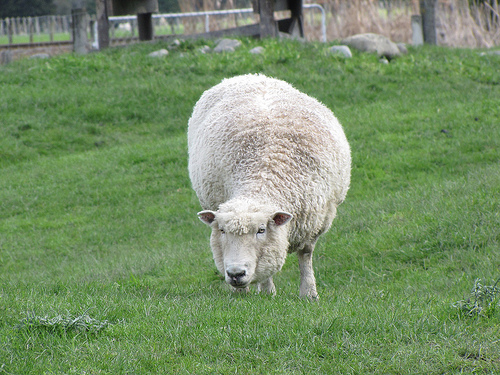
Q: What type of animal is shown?
A: Sheep.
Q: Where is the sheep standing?
A: Field.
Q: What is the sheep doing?
A: Grazing.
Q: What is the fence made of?
A: Wood.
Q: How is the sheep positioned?
A: Standing.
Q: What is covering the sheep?
A: Wool.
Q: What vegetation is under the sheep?
A: Grass.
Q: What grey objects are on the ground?
A: Boulders.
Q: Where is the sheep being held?
A: Pen.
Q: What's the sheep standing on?
A: Grass.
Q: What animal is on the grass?
A: Sheep.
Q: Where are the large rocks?
A: Behind sheep.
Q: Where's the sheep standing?
A: In a field.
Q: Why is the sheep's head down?
A: To eat.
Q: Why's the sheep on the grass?
A: To eat.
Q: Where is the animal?
A: In the field.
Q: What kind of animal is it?
A: A sheep.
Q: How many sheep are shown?
A: One.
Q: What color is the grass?
A: Green.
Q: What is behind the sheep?
A: A fence.